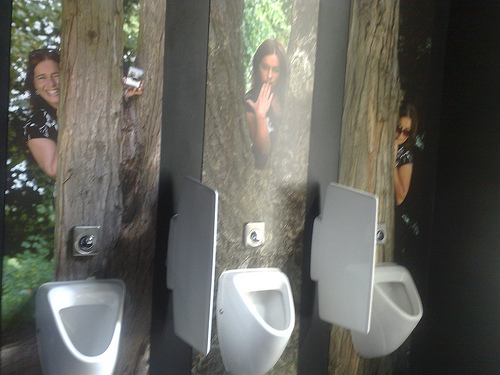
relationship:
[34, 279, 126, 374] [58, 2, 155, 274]
urinal mounted on a tree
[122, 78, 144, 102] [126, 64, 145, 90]
hand holding onto a picture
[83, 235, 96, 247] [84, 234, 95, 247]
push button that silver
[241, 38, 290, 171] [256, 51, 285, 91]
person who acting surprised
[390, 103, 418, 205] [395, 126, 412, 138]
woman who wearing sunglasses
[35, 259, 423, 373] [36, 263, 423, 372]
three urinals in a row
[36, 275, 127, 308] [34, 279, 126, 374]
top of urinal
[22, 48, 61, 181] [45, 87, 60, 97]
person who smiling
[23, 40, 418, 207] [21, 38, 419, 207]
three women in a row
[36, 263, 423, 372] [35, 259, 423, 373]
row of three urinals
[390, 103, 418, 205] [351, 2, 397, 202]
woman behind a tree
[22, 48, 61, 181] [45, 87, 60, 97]
person with a smile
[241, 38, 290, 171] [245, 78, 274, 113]
person with her hand on her mouth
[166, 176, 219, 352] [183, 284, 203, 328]
urinal divider that white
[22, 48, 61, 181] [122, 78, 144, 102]
person holding a photo in hand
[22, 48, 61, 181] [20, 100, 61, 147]
person who wearing a black dress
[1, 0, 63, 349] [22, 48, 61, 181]
plants behind person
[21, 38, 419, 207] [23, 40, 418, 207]
row of three women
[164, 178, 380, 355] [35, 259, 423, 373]
two dividers off three urinals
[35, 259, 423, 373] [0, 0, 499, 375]
three urinals in a bathroom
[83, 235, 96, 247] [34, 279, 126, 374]
push button for urinal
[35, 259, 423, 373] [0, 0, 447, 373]
three urinals on a wall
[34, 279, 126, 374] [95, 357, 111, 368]
urinal that white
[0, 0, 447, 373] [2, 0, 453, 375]
wall that covered by a picture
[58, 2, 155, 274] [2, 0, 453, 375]
tree in picture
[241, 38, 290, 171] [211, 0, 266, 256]
person behind a tree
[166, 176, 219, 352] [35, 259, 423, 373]
urinal divider between three urinals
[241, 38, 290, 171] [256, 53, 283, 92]
person who looks like shes laughing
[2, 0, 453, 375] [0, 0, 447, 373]
picture on wall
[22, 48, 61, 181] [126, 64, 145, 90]
person on end holding a picture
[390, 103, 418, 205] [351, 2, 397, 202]
woman peeking out from tree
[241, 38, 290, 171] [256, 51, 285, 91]
person who surprised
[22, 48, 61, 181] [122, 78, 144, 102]
person holding something in her hand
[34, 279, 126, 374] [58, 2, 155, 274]
urinal appears attached to tree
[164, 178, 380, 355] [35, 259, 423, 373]
two dividers between three urinals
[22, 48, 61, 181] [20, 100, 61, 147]
person has a black & white shirt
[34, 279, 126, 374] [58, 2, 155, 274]
urinal on tree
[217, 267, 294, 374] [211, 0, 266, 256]
urinal on tree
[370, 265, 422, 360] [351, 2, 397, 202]
urinal on tree